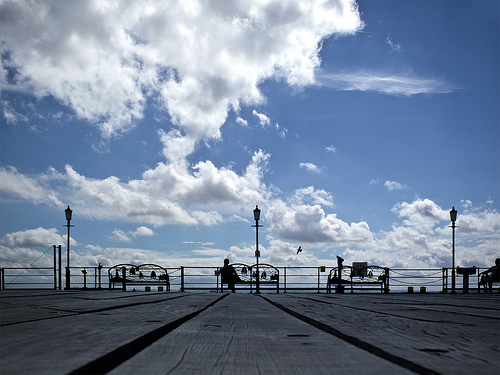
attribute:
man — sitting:
[225, 254, 245, 274]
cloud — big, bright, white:
[2, 1, 361, 138]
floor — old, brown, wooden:
[0, 288, 497, 373]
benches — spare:
[104, 260, 392, 290]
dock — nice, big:
[0, 260, 493, 372]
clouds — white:
[2, 0, 364, 140]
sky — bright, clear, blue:
[8, 1, 496, 290]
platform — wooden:
[0, 284, 494, 371]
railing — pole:
[11, 258, 45, 293]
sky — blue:
[366, 109, 433, 167]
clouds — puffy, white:
[127, 73, 261, 141]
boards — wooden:
[141, 296, 343, 366]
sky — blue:
[330, 92, 432, 195]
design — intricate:
[96, 258, 164, 290]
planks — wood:
[124, 317, 270, 371]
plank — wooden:
[205, 291, 335, 348]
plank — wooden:
[158, 317, 281, 351]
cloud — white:
[110, 44, 255, 116]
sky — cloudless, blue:
[359, 93, 472, 177]